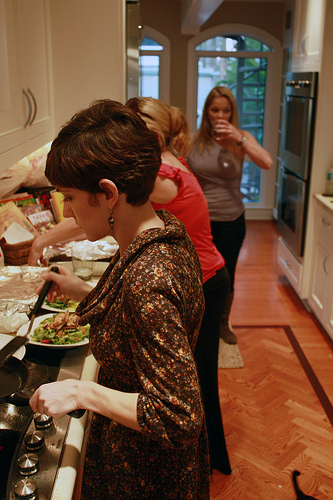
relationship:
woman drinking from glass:
[188, 85, 268, 345] [213, 119, 227, 143]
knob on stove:
[19, 427, 49, 450] [0, 357, 97, 495]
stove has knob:
[0, 295, 98, 495] [32, 412, 63, 437]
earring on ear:
[105, 210, 116, 237] [95, 176, 120, 211]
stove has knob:
[0, 348, 85, 500] [11, 478, 39, 497]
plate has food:
[15, 310, 91, 348] [33, 311, 91, 342]